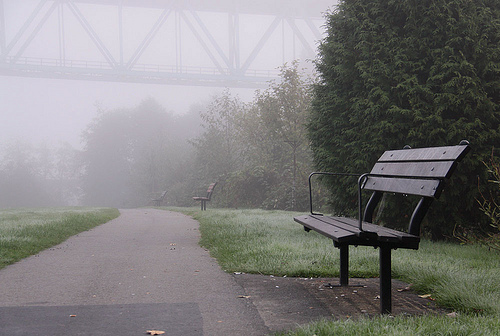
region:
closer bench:
[285, 131, 475, 321]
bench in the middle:
[190, 175, 221, 214]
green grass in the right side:
[145, 185, 490, 326]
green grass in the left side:
[0, 190, 120, 281]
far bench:
[150, 181, 165, 216]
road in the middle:
[6, 182, 256, 332]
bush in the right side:
[302, 2, 493, 218]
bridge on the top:
[0, 0, 416, 85]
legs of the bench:
[322, 235, 403, 307]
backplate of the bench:
[358, 143, 469, 202]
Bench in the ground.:
[229, 117, 494, 298]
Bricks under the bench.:
[286, 256, 407, 331]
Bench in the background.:
[155, 142, 259, 272]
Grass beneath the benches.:
[156, 200, 377, 331]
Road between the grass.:
[13, 194, 370, 283]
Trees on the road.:
[216, 47, 411, 214]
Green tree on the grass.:
[294, 10, 473, 236]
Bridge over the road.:
[28, 10, 292, 137]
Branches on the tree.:
[175, 90, 319, 203]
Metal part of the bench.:
[293, 142, 489, 289]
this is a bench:
[306, 153, 438, 277]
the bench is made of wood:
[386, 161, 426, 173]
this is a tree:
[346, 15, 492, 134]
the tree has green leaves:
[366, 57, 396, 92]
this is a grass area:
[232, 216, 284, 256]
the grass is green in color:
[231, 230, 286, 259]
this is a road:
[63, 242, 176, 298]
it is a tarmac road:
[56, 264, 181, 306]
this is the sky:
[10, 85, 81, 130]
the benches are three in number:
[146, 177, 418, 234]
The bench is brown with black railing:
[269, 142, 468, 320]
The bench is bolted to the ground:
[313, 265, 436, 321]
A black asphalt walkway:
[43, 172, 260, 332]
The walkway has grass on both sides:
[26, 187, 480, 326]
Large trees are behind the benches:
[63, 22, 478, 252]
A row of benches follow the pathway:
[100, 131, 453, 311]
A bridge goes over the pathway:
[27, 6, 339, 100]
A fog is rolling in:
[21, 9, 406, 239]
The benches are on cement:
[228, 240, 468, 328]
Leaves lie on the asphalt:
[68, 255, 471, 329]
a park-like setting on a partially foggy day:
[6, 3, 486, 325]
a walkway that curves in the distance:
[50, 200, 220, 333]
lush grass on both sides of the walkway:
[2, 206, 287, 264]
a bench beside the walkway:
[157, 140, 472, 331]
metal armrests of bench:
[302, 163, 429, 233]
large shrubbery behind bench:
[315, 1, 496, 292]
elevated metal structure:
[0, 0, 335, 95]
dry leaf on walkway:
[131, 317, 168, 332]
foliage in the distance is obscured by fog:
[5, 88, 192, 208]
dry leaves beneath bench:
[339, 229, 440, 314]